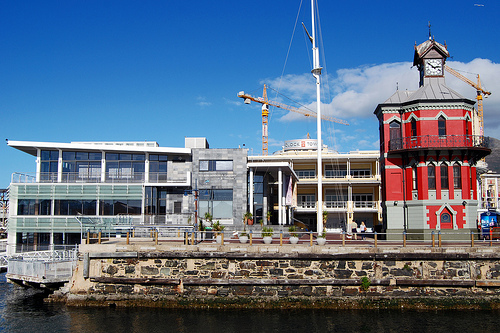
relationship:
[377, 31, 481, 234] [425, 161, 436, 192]
building has window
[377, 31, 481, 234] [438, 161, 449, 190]
building has window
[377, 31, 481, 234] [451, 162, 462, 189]
building has window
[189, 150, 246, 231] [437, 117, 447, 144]
building has window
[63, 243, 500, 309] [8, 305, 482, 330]
wall by water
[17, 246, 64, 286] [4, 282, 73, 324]
boat sitting in water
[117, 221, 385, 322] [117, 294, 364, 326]
wall at water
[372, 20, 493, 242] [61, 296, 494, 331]
building by water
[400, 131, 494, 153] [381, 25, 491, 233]
balcony on a building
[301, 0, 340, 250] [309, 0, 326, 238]
white mast or white mast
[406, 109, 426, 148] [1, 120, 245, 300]
window on building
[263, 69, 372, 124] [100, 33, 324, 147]
cloud in sky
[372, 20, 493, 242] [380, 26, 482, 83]
building has clock